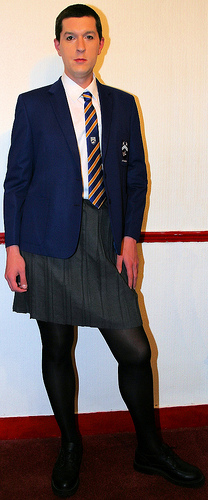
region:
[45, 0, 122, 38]
man's short black hair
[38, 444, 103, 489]
shiny black patent shoes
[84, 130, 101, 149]
logo on neck tie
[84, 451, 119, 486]
red carpet on the floor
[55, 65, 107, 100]
collar on white shirt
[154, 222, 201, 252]
red wood on the wall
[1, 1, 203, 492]
A man wearing a skirt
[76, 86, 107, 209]
Blue and yellow stripes on a tie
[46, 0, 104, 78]
Black hair on man's head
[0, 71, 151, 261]
A blue colored jacket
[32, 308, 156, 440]
A pair of black stockings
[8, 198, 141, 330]
The skirt is gray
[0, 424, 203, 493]
Maroon carpet on the floor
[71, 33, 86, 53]
Nose on man's face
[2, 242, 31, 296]
Right hand of a man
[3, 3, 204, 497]
man standing against light colored wall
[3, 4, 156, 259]
man in blue jacket and striped tie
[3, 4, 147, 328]
man in gray pleated skirt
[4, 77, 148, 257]
blue jacket with emblem on chest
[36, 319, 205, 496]
two legs in black nylons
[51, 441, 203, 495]
a pair of black shoes with laces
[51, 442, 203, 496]
a pair of black shoes with thick soles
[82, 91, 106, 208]
blue tie with yellow stripes and emblem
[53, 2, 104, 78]
man with short dark hair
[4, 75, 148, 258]
white shirt with collar under jacket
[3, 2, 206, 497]
this is a person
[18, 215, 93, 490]
this is a person's leg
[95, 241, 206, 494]
this is a person's leg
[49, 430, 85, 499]
this is a person's shoe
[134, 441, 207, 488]
this is a person's shoe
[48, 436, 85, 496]
this is a black shoe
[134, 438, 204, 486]
this is a black shoe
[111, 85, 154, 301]
this is a person's hand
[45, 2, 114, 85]
this is a person's head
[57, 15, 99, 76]
this is a person's face